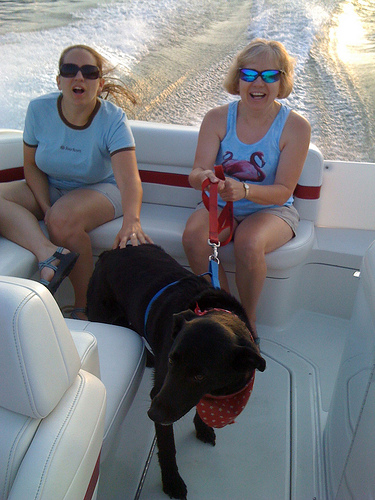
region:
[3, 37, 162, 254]
woman wearing blue shirt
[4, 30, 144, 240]
woman wearing khaki shorts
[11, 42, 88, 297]
woman sitting in a boat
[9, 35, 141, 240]
woman wearing sun shades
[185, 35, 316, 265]
woman wearing a tank top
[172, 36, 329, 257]
woman wearing khaki shorts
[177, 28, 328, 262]
woman wearing sun shades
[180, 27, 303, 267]
woman sitting in a boat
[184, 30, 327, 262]
woman holding dog leash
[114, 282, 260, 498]
dog standing in a boat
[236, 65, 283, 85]
The woman is wearing sunglasses.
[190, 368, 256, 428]
The dog is wearing a red bandana.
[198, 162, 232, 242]
Part of the leash is red.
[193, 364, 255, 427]
The bandana has white dots on it.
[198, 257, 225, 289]
Part of the leash is blue.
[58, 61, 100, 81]
The woman is wearing sunglasses.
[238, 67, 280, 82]
The sunglasses are blue.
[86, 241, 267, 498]
The dogs is black.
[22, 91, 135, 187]
The woman wears a gray shirt.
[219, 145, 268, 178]
Flamingos are on the tank top.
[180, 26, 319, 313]
Lady sitting in the boat holding the dog leash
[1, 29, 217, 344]
lady sitting in the boat holding the dog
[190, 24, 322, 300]
lady sitting on the boat wearing sunglasses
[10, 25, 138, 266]
lady on a pony tail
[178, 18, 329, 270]
lady wearing a sleeveless shirt and brown shorts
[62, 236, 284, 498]
black dog with polka dot tie on the neck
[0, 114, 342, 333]
the boat with leather white seat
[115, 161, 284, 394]
Dog with blue and red leash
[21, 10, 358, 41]
bubbles on the ocean while the boat passed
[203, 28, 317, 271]
lady with gold watch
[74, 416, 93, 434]
part of a chair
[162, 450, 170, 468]
leg of a dog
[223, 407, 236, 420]
part of a clothe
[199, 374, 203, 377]
eye of a dog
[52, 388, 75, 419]
edge of a seat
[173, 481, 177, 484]
tip of a leg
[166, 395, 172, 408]
head of a cow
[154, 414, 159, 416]
mouth of a dog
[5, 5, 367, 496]
two women and a dog on a boat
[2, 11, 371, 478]
the boat is moving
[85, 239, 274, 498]
a dog is on the boat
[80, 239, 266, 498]
the dog is brown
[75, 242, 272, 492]
the dog has a red and white bandana around it's neck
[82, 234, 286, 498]
the dog has a blue leach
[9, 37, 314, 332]
the women are wearing sunglases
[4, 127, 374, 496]
the boat cushions are white with red stripes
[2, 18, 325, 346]
the women are sitting on a boat seat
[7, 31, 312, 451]
the women are looking at the camera